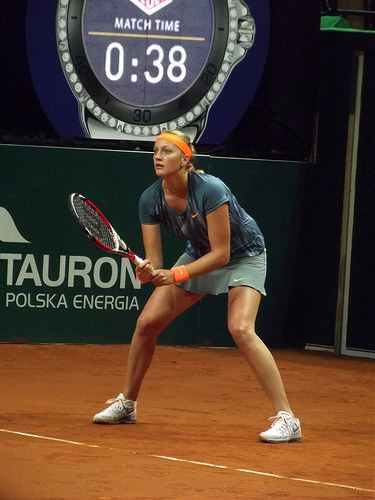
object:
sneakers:
[258, 409, 304, 447]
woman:
[91, 129, 302, 444]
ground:
[2, 341, 374, 499]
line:
[0, 425, 374, 493]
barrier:
[2, 140, 313, 351]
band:
[171, 263, 192, 284]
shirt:
[137, 173, 265, 266]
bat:
[70, 189, 169, 290]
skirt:
[167, 249, 267, 297]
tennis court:
[0, 2, 373, 497]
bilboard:
[53, 0, 257, 144]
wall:
[0, 3, 345, 342]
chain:
[157, 179, 188, 196]